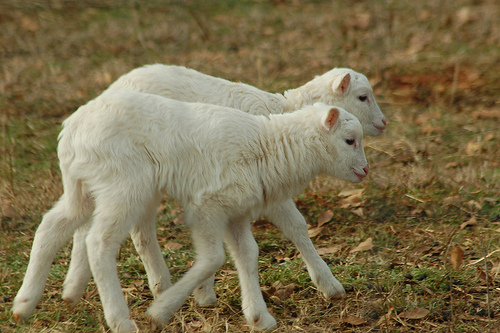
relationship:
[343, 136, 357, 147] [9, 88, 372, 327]
eye of sheep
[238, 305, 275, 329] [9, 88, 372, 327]
paw of sheep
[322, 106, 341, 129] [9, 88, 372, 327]
ear of sheep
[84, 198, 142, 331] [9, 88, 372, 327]
leg of sheep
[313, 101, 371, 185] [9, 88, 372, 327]
head of sheep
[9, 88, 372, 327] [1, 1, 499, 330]
sheep standing on grass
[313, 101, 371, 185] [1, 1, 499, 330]
head near grass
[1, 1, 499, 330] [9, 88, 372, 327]
grass under sheep